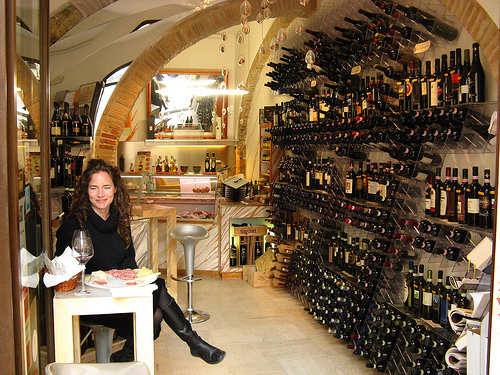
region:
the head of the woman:
[79, 157, 121, 215]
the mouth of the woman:
[93, 195, 110, 206]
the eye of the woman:
[101, 183, 112, 190]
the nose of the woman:
[95, 186, 105, 198]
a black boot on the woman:
[158, 295, 230, 368]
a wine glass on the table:
[68, 234, 98, 298]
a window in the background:
[145, 64, 230, 145]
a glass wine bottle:
[399, 257, 419, 311]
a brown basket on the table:
[46, 266, 86, 299]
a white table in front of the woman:
[47, 265, 160, 374]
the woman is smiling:
[55, 156, 128, 219]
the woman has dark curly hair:
[72, 165, 149, 260]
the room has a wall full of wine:
[240, 22, 484, 350]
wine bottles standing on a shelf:
[413, 159, 494, 231]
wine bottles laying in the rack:
[298, 255, 384, 347]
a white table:
[42, 275, 157, 373]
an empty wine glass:
[57, 237, 108, 299]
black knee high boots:
[156, 289, 230, 371]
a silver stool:
[167, 222, 219, 327]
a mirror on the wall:
[125, 58, 244, 149]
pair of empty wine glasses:
[66, 224, 101, 295]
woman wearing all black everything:
[44, 161, 226, 371]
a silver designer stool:
[166, 216, 216, 327]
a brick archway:
[87, 0, 319, 170]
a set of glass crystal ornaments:
[194, 0, 331, 147]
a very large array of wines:
[257, 4, 494, 374]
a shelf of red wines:
[47, 96, 100, 145]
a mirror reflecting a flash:
[127, 59, 239, 147]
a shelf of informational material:
[439, 225, 484, 373]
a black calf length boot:
[156, 294, 228, 368]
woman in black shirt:
[64, 132, 151, 279]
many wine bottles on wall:
[225, 32, 452, 370]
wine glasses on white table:
[62, 227, 119, 312]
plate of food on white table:
[100, 257, 158, 298]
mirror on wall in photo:
[134, 57, 249, 159]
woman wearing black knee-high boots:
[138, 274, 248, 374]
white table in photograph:
[54, 242, 166, 373]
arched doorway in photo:
[108, 1, 372, 201]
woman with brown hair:
[72, 150, 153, 247]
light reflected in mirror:
[148, 62, 266, 156]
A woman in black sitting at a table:
[52, 162, 179, 374]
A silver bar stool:
[169, 219, 221, 329]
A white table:
[38, 279, 155, 374]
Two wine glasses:
[67, 229, 107, 301]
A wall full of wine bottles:
[260, 7, 494, 372]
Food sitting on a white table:
[44, 251, 166, 316]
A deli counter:
[122, 176, 219, 218]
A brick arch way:
[72, 4, 313, 166]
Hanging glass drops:
[212, 3, 319, 142]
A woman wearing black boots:
[68, 154, 232, 367]